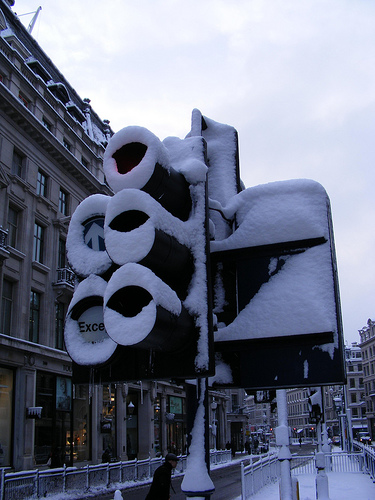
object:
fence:
[0, 447, 232, 497]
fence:
[239, 447, 292, 496]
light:
[97, 100, 327, 386]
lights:
[270, 427, 273, 431]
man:
[146, 453, 181, 499]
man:
[245, 441, 253, 456]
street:
[78, 443, 319, 500]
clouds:
[9, 0, 374, 352]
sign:
[74, 297, 106, 351]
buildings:
[0, 1, 372, 498]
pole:
[181, 375, 216, 499]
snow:
[179, 379, 215, 491]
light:
[311, 427, 313, 430]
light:
[293, 427, 296, 431]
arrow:
[85, 222, 105, 252]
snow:
[252, 182, 313, 235]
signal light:
[64, 106, 215, 385]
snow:
[85, 199, 105, 212]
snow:
[278, 270, 332, 322]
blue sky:
[0, 0, 374, 346]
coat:
[145, 461, 173, 500]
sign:
[212, 178, 347, 390]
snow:
[103, 263, 180, 346]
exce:
[78, 322, 105, 333]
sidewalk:
[3, 435, 242, 496]